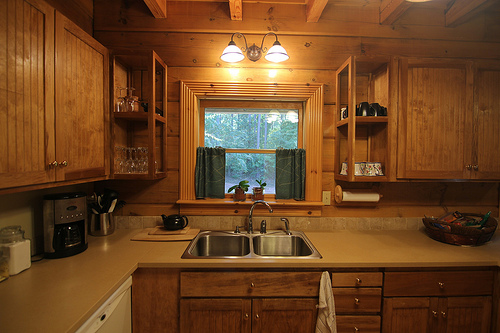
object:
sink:
[182, 201, 321, 259]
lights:
[219, 42, 245, 64]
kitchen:
[2, 2, 500, 332]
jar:
[2, 227, 32, 277]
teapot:
[160, 211, 189, 234]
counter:
[2, 217, 500, 332]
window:
[197, 98, 309, 203]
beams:
[142, 1, 490, 26]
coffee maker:
[35, 194, 89, 258]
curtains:
[194, 147, 305, 199]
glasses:
[115, 144, 151, 175]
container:
[89, 210, 112, 235]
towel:
[316, 270, 336, 331]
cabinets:
[2, 3, 113, 195]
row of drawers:
[327, 285, 382, 314]